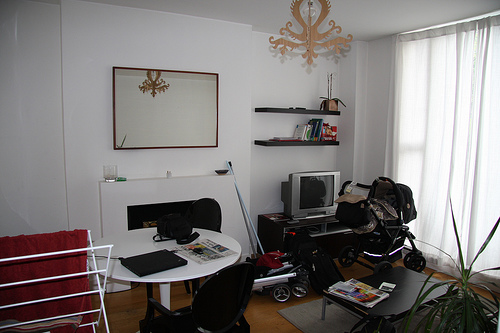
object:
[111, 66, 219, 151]
mirror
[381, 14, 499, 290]
drape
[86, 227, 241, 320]
table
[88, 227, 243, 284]
top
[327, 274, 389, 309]
magazine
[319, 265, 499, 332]
table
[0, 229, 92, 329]
blanket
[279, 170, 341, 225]
television set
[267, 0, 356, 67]
light fixture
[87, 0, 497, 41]
ceiling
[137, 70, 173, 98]
reflection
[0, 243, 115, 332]
blanket rack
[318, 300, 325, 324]
legs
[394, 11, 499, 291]
window